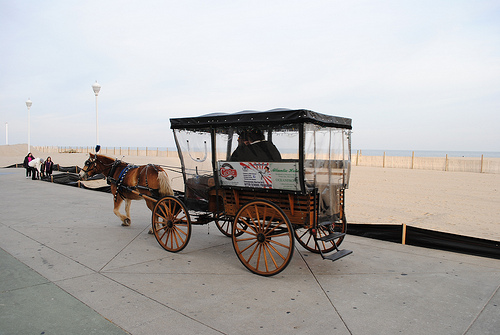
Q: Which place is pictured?
A: It is a pavement.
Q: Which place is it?
A: It is a pavement.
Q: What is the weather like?
A: It is cloudy.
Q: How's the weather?
A: It is cloudy.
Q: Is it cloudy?
A: Yes, it is cloudy.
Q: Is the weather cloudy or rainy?
A: It is cloudy.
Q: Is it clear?
A: No, it is cloudy.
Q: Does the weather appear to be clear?
A: No, it is cloudy.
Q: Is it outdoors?
A: Yes, it is outdoors.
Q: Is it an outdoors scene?
A: Yes, it is outdoors.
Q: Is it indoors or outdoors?
A: It is outdoors.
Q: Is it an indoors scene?
A: No, it is outdoors.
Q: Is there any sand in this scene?
A: Yes, there is sand.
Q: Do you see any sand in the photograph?
A: Yes, there is sand.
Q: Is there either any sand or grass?
A: Yes, there is sand.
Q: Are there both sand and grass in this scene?
A: No, there is sand but no grass.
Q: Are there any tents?
A: No, there are no tents.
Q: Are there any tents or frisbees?
A: No, there are no tents or frisbees.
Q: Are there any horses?
A: Yes, there is a horse.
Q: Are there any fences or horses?
A: Yes, there is a horse.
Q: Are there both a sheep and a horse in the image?
A: No, there is a horse but no sheep.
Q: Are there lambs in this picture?
A: No, there are no lambs.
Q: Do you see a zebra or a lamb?
A: No, there are no lambs or zebras.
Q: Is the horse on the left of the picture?
A: Yes, the horse is on the left of the image.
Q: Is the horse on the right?
A: No, the horse is on the left of the image.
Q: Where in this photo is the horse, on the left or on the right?
A: The horse is on the left of the image.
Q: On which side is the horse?
A: The horse is on the left of the image.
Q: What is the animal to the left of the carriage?
A: The animal is a horse.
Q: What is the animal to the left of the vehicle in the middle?
A: The animal is a horse.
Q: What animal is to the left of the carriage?
A: The animal is a horse.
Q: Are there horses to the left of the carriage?
A: Yes, there is a horse to the left of the carriage.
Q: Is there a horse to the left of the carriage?
A: Yes, there is a horse to the left of the carriage.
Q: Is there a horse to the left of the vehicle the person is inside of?
A: Yes, there is a horse to the left of the carriage.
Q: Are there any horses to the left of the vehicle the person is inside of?
A: Yes, there is a horse to the left of the carriage.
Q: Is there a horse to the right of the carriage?
A: No, the horse is to the left of the carriage.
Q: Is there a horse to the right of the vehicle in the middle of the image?
A: No, the horse is to the left of the carriage.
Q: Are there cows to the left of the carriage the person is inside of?
A: No, there is a horse to the left of the carriage.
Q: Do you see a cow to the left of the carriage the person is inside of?
A: No, there is a horse to the left of the carriage.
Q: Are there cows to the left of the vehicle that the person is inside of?
A: No, there is a horse to the left of the carriage.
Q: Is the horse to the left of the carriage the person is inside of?
A: Yes, the horse is to the left of the carriage.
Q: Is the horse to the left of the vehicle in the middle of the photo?
A: Yes, the horse is to the left of the carriage.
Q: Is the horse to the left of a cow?
A: No, the horse is to the left of the carriage.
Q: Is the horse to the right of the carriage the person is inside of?
A: No, the horse is to the left of the carriage.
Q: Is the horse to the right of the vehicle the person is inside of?
A: No, the horse is to the left of the carriage.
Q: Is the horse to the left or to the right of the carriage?
A: The horse is to the left of the carriage.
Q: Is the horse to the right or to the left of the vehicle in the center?
A: The horse is to the left of the carriage.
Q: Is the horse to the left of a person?
A: No, the horse is to the right of a person.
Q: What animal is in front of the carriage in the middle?
A: The horse is in front of the carriage.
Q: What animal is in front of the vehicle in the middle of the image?
A: The horse is in front of the carriage.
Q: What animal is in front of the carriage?
A: The horse is in front of the carriage.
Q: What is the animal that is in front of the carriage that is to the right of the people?
A: The animal is a horse.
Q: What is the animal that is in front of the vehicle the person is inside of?
A: The animal is a horse.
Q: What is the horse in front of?
A: The horse is in front of the carriage.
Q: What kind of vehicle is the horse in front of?
A: The horse is in front of the carriage.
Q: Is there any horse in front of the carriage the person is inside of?
A: Yes, there is a horse in front of the carriage.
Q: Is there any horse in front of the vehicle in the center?
A: Yes, there is a horse in front of the carriage.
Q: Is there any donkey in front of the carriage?
A: No, there is a horse in front of the carriage.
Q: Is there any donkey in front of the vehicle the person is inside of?
A: No, there is a horse in front of the carriage.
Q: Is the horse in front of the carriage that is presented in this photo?
A: Yes, the horse is in front of the carriage.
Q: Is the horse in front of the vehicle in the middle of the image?
A: Yes, the horse is in front of the carriage.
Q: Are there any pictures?
A: No, there are no pictures.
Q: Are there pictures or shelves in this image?
A: No, there are no pictures or shelves.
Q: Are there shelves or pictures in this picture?
A: No, there are no pictures or shelves.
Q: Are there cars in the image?
A: No, there are no cars.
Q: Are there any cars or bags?
A: No, there are no cars or bags.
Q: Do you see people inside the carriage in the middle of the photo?
A: Yes, there is a person inside the carriage.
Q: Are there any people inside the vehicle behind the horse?
A: Yes, there is a person inside the carriage.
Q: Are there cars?
A: No, there are no cars.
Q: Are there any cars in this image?
A: No, there are no cars.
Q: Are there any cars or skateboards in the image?
A: No, there are no cars or skateboards.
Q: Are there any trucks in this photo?
A: No, there are no trucks.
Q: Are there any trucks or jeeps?
A: No, there are no trucks or jeeps.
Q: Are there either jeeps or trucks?
A: No, there are no trucks or jeeps.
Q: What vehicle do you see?
A: The vehicle is a carriage.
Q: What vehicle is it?
A: The vehicle is a carriage.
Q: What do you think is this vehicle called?
A: This is a carriage.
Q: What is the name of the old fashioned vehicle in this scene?
A: The vehicle is a carriage.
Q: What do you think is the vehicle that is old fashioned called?
A: The vehicle is a carriage.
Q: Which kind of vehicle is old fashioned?
A: The vehicle is a carriage.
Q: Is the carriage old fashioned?
A: Yes, the carriage is old fashioned.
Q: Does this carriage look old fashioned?
A: Yes, the carriage is old fashioned.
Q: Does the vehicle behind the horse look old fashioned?
A: Yes, the carriage is old fashioned.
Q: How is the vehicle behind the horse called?
A: The vehicle is a carriage.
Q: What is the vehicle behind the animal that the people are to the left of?
A: The vehicle is a carriage.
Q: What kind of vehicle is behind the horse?
A: The vehicle is a carriage.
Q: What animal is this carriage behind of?
A: The carriage is behind the horse.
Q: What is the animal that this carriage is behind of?
A: The animal is a horse.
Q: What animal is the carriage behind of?
A: The carriage is behind the horse.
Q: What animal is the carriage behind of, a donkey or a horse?
A: The carriage is behind a horse.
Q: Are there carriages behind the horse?
A: Yes, there is a carriage behind the horse.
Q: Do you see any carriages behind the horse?
A: Yes, there is a carriage behind the horse.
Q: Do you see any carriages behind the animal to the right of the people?
A: Yes, there is a carriage behind the horse.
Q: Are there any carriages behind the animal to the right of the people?
A: Yes, there is a carriage behind the horse.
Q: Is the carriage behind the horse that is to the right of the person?
A: Yes, the carriage is behind the horse.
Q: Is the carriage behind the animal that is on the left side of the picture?
A: Yes, the carriage is behind the horse.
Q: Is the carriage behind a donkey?
A: No, the carriage is behind the horse.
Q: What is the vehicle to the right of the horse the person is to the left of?
A: The vehicle is a carriage.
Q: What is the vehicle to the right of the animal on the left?
A: The vehicle is a carriage.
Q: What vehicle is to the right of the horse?
A: The vehicle is a carriage.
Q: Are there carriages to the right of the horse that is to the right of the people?
A: Yes, there is a carriage to the right of the horse.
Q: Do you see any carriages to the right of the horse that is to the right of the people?
A: Yes, there is a carriage to the right of the horse.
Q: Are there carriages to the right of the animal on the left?
A: Yes, there is a carriage to the right of the horse.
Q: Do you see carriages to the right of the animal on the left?
A: Yes, there is a carriage to the right of the horse.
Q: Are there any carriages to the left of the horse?
A: No, the carriage is to the right of the horse.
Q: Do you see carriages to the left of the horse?
A: No, the carriage is to the right of the horse.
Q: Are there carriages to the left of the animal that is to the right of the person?
A: No, the carriage is to the right of the horse.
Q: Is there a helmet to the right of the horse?
A: No, there is a carriage to the right of the horse.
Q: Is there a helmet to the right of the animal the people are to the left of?
A: No, there is a carriage to the right of the horse.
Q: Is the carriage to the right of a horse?
A: Yes, the carriage is to the right of a horse.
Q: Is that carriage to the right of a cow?
A: No, the carriage is to the right of a horse.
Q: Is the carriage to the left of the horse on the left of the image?
A: No, the carriage is to the right of the horse.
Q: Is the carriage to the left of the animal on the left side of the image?
A: No, the carriage is to the right of the horse.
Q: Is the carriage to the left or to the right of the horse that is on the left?
A: The carriage is to the right of the horse.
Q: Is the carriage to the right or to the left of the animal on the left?
A: The carriage is to the right of the horse.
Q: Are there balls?
A: No, there are no balls.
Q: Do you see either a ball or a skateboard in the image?
A: No, there are no balls or skateboards.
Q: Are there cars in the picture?
A: No, there are no cars.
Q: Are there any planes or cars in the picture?
A: No, there are no cars or planes.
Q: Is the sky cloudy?
A: Yes, the sky is cloudy.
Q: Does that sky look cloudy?
A: Yes, the sky is cloudy.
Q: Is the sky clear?
A: No, the sky is cloudy.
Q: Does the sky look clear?
A: No, the sky is cloudy.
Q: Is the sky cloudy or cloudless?
A: The sky is cloudy.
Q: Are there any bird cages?
A: No, there are no bird cages.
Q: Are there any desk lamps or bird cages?
A: No, there are no bird cages or desk lamps.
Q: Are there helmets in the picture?
A: No, there are no helmets.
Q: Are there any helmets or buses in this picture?
A: No, there are no helmets or buses.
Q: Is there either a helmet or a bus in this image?
A: No, there are no helmets or buses.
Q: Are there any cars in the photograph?
A: No, there are no cars.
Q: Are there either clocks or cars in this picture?
A: No, there are no cars or clocks.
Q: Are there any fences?
A: Yes, there is a fence.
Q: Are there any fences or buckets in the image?
A: Yes, there is a fence.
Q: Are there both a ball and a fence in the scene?
A: No, there is a fence but no balls.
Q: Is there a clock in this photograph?
A: No, there are no clocks.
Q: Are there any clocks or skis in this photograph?
A: No, there are no clocks or skis.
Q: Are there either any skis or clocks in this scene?
A: No, there are no clocks or skis.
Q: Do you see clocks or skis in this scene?
A: No, there are no clocks or skis.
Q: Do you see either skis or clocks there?
A: No, there are no clocks or skis.